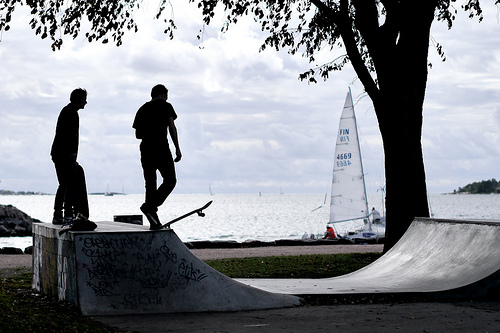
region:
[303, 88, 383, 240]
A sailboat on the water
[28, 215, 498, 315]
A small halfpipe by the water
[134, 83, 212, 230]
A man preparing to ride a skateboard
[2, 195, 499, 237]
A body of water beneath the boat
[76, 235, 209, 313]
Graffiti on the halfpipe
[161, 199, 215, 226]
A skateboard on the halfpipe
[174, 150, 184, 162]
The left hand of the man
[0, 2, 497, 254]
A tree near the halfpipe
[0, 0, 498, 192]
The sky above the water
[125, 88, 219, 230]
The man has a moment to think before he skates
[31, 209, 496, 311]
The skate rakmps are made of cement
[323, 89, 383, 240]
The white sailboat is in the water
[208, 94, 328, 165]
The rain clouds are full of moisture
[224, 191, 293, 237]
The lake water is peaceful and calm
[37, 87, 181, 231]
The two men are friends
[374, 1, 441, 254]
The big tree offers lots of shade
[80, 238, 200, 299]
Graffitti is common at the skate park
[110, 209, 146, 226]
Public trash barrels keep people from littering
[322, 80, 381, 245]
people on a sail boat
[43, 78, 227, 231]
a dark shadow of skaters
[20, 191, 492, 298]
a ramp for skaters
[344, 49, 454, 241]
a tree over the ramp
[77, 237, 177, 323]
graffiti on the ramp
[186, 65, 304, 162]
a overcast sky full of clouds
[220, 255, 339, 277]
a patch of green grass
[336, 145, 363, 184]
id numbers on sail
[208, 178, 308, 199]
boats on the horizon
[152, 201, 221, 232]
a small black skateboard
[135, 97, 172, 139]
the shirt of a skateboarder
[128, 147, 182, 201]
the pants of a skateboarder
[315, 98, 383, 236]
the sail of a boat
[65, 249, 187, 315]
a bunch of random graffiti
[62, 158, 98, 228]
a guy holding a skateboard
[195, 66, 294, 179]
a bunch of clouds in the sky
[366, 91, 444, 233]
the thick trunk of a tree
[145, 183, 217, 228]
a skateboard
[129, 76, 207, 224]
a man standing atop of the ramp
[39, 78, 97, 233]
a man standing atop of the ramp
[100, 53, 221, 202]
person on the skateboard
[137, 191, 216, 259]
skateboard under the person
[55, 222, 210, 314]
side of the ramp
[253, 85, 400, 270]
boat in the water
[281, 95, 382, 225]
white sail on the boat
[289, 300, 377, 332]
ground next to ramp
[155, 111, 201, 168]
arm of the skater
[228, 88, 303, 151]
clouds in the sky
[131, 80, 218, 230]
guy on a skateboard about to go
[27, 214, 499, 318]
skateboard ramp with graffiti on it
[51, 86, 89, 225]
man holding a skateboard in his hand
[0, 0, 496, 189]
the sky is cloudy and blue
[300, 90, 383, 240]
sailboat with someone in orange on it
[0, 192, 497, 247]
the ocean with sailboats in it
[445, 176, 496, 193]
trees in the distance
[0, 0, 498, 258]
very dark tree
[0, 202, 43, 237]
pile of rocks in the ocean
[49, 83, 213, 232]
guys that are skateboarding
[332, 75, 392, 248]
a sail boat on the edge of the water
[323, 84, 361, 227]
the sail is white with black writing